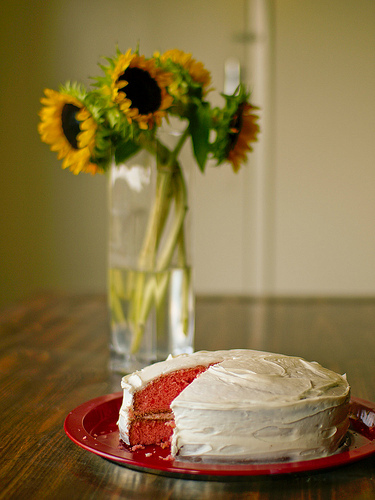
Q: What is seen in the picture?
A: Cake.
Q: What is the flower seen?
A: Sunflower.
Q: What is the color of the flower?
A: Yellow and brown.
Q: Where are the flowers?
A: In the vase.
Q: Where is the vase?
A: In the table.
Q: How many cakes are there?
A: 1.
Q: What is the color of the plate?
A: Red.